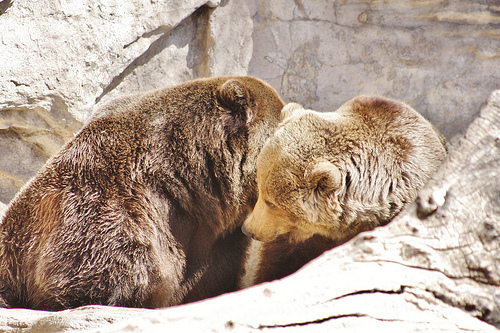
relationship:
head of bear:
[235, 98, 362, 263] [231, 88, 443, 258]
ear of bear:
[303, 161, 342, 193] [231, 88, 443, 258]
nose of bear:
[237, 217, 281, 244] [231, 88, 443, 258]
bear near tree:
[231, 88, 443, 258] [232, 119, 497, 325]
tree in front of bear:
[232, 119, 497, 325] [231, 88, 443, 258]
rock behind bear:
[2, 2, 498, 192] [231, 88, 443, 258]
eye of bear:
[264, 199, 278, 214] [231, 88, 443, 258]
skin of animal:
[6, 82, 269, 302] [2, 76, 287, 307]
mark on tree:
[256, 300, 426, 327] [232, 119, 497, 325]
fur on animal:
[6, 80, 261, 304] [2, 76, 287, 307]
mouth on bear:
[246, 226, 310, 246] [231, 88, 443, 258]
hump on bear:
[340, 93, 441, 161] [231, 88, 443, 258]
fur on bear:
[303, 95, 443, 235] [231, 88, 443, 258]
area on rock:
[359, 231, 499, 285] [2, 2, 498, 192]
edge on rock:
[357, 88, 497, 243] [2, 2, 498, 192]